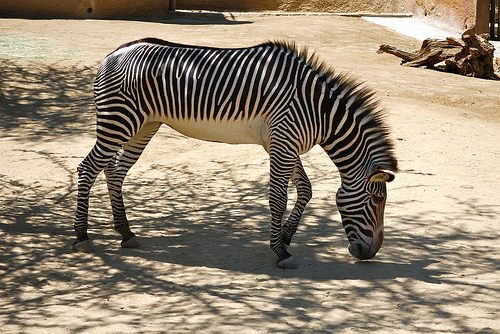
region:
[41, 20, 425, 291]
a zebra in a zoo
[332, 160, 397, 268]
the head of a zebra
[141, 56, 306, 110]
the stripes of a zebra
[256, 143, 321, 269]
the front legs of a zebra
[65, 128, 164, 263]
the rear legs of a zebra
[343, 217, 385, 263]
the nose of a zebra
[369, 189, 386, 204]
the eye of a zebra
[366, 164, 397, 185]
the ear of a zebra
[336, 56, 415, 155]
the mane of a zebra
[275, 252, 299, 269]
the hoof of a zebra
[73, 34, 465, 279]
a zebra in a field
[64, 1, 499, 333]
a zebra in a dirt field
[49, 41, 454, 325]
a zebra standign outside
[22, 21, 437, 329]
zebra standing in a dirt field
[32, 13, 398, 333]
a zebra with head down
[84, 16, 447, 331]
a black and white zebra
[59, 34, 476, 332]
a field with zebra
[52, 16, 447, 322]
a dirt field with zebra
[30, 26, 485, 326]
an area with zebra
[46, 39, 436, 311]
zebra that is outside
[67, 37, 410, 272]
Zebra with black and white stripes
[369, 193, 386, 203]
Zebra's eye which is black in color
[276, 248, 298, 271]
Front right hoof of zebra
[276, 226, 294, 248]
Front left hoof of the zebra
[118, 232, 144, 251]
Back left hoof of zebra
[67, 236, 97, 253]
Back right hoof of zebra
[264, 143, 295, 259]
Front right leg of zebra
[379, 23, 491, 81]
Pile of wood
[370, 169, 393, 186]
Front right zebra ear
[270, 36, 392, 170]
Zebra's black and white mane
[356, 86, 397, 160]
hair from the mane sticking straight up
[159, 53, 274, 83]
stripes on the zebra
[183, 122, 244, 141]
white belly of the zebra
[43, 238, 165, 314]
shadow of a tree on the ground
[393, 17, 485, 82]
dead wood behind the zebra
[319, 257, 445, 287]
shadow of the zebra's head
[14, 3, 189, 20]
building in the background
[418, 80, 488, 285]
dirt area around the zebra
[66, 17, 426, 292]
zebra sniffing the ground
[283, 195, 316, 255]
zebra's hoof is raised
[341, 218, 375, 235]
black stripe on zebra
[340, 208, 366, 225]
black stripe on zebra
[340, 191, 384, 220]
black stripe on zebra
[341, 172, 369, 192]
black stripe on zebra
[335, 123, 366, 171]
black stripe on zebra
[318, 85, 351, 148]
black stripe on zebra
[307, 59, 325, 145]
black stripe on zebra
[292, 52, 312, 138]
black stripe on zebra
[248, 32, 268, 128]
black stripe on zebra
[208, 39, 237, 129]
black stripe on zebra